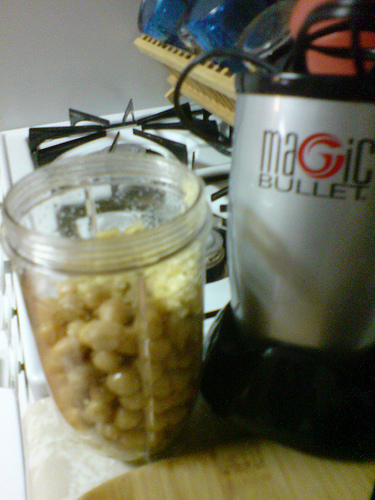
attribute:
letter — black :
[328, 136, 374, 184]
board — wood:
[33, 443, 147, 492]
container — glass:
[0, 154, 214, 460]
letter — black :
[328, 180, 349, 201]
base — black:
[201, 304, 370, 468]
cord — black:
[171, 1, 372, 147]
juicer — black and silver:
[193, 65, 373, 463]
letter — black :
[294, 173, 310, 197]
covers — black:
[26, 95, 225, 161]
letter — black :
[347, 179, 373, 204]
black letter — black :
[343, 135, 355, 188]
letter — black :
[263, 125, 279, 173]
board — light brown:
[76, 429, 372, 499]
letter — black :
[268, 129, 290, 185]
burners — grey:
[24, 93, 231, 182]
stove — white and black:
[9, 96, 238, 169]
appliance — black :
[218, 55, 373, 469]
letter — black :
[259, 124, 282, 179]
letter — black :
[280, 129, 299, 180]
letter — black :
[342, 133, 357, 187]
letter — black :
[350, 134, 373, 191]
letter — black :
[256, 172, 272, 195]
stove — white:
[13, 113, 249, 277]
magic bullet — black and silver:
[193, 68, 374, 444]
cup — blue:
[134, 0, 191, 44]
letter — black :
[301, 174, 337, 204]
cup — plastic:
[65, 249, 190, 401]